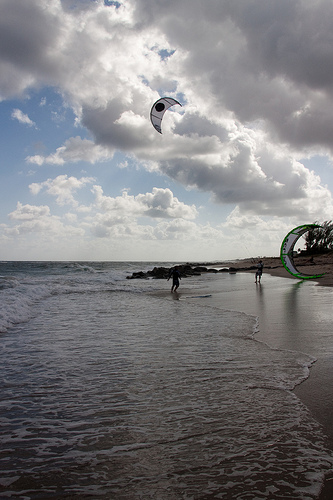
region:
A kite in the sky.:
[149, 96, 182, 134]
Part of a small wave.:
[0, 287, 37, 321]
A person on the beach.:
[168, 266, 183, 293]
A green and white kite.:
[279, 223, 325, 279]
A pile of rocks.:
[127, 263, 235, 279]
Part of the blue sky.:
[11, 134, 46, 143]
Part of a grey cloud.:
[264, 18, 310, 67]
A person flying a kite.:
[254, 259, 263, 281]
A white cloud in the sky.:
[8, 201, 49, 220]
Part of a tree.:
[309, 230, 330, 245]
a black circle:
[154, 102, 164, 111]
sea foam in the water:
[3, 363, 271, 498]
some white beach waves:
[0, 272, 76, 327]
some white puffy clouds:
[7, 175, 212, 245]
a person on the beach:
[167, 266, 182, 292]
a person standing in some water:
[168, 265, 181, 293]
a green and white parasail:
[279, 221, 329, 279]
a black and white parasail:
[148, 95, 182, 135]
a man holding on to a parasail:
[149, 96, 264, 283]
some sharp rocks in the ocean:
[129, 261, 209, 278]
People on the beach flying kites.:
[163, 97, 271, 289]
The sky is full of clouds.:
[70, 120, 275, 207]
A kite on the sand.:
[280, 223, 307, 278]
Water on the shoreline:
[123, 312, 312, 481]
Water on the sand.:
[211, 292, 315, 464]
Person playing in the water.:
[146, 258, 183, 307]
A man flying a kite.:
[247, 251, 267, 280]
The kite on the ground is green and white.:
[278, 221, 332, 289]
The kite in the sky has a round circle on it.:
[152, 66, 193, 141]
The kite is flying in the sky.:
[142, 87, 206, 131]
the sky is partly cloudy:
[16, 2, 325, 212]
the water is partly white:
[44, 305, 306, 471]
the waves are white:
[4, 274, 90, 346]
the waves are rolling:
[1, 255, 118, 323]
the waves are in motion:
[41, 248, 135, 306]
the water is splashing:
[11, 228, 138, 307]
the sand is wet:
[221, 260, 321, 351]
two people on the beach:
[140, 215, 328, 299]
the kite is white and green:
[259, 196, 326, 292]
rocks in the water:
[92, 249, 216, 282]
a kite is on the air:
[151, 95, 179, 132]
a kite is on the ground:
[278, 223, 326, 277]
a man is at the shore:
[167, 268, 179, 293]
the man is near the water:
[169, 267, 180, 294]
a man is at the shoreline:
[255, 257, 266, 283]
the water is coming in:
[139, 266, 332, 443]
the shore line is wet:
[186, 267, 332, 398]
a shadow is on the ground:
[253, 280, 267, 324]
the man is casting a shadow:
[252, 259, 265, 306]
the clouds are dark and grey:
[0, 2, 328, 230]